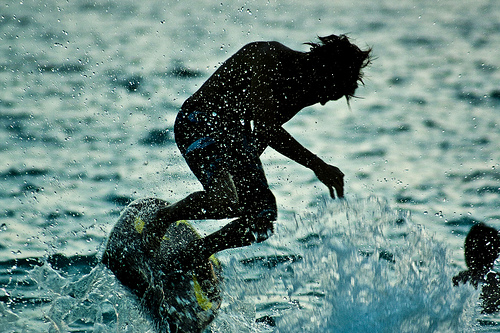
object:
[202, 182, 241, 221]
knee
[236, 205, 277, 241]
knee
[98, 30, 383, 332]
surfing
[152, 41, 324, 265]
wet suit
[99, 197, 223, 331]
surfboard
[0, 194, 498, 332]
waves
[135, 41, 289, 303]
mist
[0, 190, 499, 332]
splash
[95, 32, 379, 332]
exercise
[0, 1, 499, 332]
picture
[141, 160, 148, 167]
bubbles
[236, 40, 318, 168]
arm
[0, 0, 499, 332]
water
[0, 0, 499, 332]
lens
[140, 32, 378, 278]
guy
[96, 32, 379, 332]
silhouette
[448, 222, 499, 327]
object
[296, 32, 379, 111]
hair